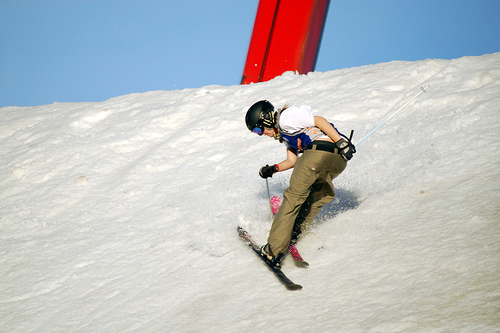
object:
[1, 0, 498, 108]
sky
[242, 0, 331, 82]
object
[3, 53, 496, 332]
snow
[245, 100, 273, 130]
helmet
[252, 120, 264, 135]
surfing goggles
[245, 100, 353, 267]
man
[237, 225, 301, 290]
ski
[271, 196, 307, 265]
ski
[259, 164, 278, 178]
hand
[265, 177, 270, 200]
stick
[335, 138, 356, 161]
glove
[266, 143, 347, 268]
trouser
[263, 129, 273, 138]
face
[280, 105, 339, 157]
shirt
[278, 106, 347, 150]
vest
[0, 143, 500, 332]
ground